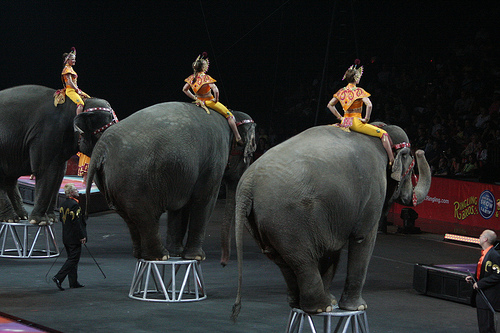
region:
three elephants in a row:
[15, 44, 459, 316]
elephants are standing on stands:
[12, 192, 388, 326]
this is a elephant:
[217, 62, 446, 301]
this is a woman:
[325, 45, 425, 192]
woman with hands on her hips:
[320, 65, 393, 153]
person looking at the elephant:
[459, 213, 497, 310]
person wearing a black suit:
[46, 190, 106, 287]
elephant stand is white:
[119, 230, 199, 317]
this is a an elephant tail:
[206, 172, 256, 329]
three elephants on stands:
[0, 85, 430, 315]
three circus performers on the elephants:
[64, 47, 395, 165]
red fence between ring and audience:
[391, 178, 499, 230]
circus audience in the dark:
[258, 60, 498, 181]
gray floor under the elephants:
[0, 215, 483, 330]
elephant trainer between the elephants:
[56, 184, 106, 290]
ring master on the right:
[466, 230, 497, 330]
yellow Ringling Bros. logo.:
[454, 188, 479, 223]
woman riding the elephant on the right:
[230, 60, 432, 331]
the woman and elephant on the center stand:
[84, 55, 255, 303]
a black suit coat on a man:
[466, 246, 499, 307]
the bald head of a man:
[477, 228, 496, 247]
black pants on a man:
[58, 236, 85, 283]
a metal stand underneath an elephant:
[122, 254, 206, 306]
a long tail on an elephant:
[230, 172, 257, 319]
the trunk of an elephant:
[412, 147, 433, 206]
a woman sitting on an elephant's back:
[321, 63, 398, 165]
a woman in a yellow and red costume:
[182, 51, 246, 146]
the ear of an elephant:
[388, 142, 414, 189]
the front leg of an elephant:
[339, 197, 384, 314]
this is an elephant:
[219, 50, 442, 329]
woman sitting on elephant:
[330, 48, 416, 162]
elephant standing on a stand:
[275, 270, 376, 331]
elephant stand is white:
[114, 234, 229, 326]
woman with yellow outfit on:
[331, 80, 407, 157]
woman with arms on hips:
[328, 77, 386, 133]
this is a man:
[462, 225, 497, 330]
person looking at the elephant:
[40, 162, 102, 294]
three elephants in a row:
[2, 42, 464, 323]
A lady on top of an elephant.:
[319, 61, 406, 137]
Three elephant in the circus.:
[21, 92, 345, 267]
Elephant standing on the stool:
[93, 102, 269, 308]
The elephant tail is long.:
[218, 209, 255, 320]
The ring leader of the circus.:
[458, 224, 498, 301]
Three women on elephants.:
[44, 47, 387, 129]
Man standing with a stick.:
[53, 178, 107, 293]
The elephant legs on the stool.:
[268, 249, 398, 309]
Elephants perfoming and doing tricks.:
[41, 80, 407, 298]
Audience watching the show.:
[406, 82, 495, 164]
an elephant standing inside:
[265, 96, 431, 296]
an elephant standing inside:
[33, 81, 96, 190]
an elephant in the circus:
[250, 139, 354, 321]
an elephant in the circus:
[131, 106, 175, 223]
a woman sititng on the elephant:
[297, 66, 418, 193]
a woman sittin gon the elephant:
[190, 31, 246, 134]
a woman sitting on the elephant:
[47, 31, 72, 103]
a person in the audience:
[438, 95, 479, 167]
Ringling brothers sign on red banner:
[441, 180, 496, 226]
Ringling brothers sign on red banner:
[446, 183, 498, 228]